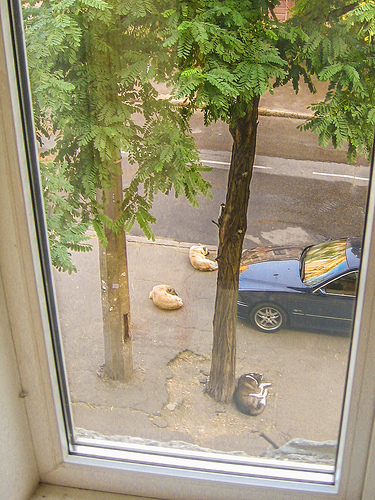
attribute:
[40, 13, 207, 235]
leaves — bright green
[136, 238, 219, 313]
dogs — light brown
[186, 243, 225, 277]
dog — sleeping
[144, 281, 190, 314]
dog — sleeping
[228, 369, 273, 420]
dog — sleeping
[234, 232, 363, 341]
car — parked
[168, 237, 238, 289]
dog — sleeping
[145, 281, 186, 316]
lab — yellow